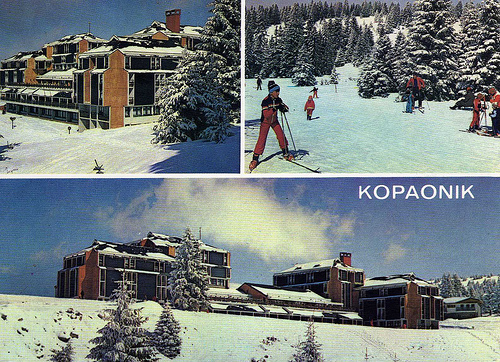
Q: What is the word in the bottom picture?
A: Kopaonik.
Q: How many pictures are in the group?
A: Three.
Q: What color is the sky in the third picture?
A: Blue.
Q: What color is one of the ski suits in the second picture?
A: Orange.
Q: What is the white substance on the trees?
A: Snow.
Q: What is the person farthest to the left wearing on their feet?
A: Skis.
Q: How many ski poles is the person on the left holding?
A: Two.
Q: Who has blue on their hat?
A: The person on the left.